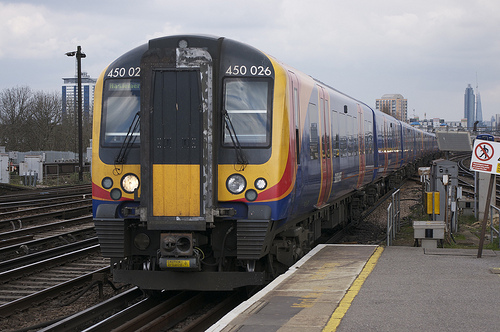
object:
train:
[90, 33, 437, 296]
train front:
[91, 36, 288, 292]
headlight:
[227, 174, 247, 193]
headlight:
[121, 173, 140, 193]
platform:
[197, 241, 499, 331]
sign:
[470, 137, 499, 176]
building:
[374, 93, 408, 125]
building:
[61, 70, 95, 124]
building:
[464, 82, 475, 132]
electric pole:
[73, 45, 86, 179]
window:
[101, 77, 139, 148]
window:
[224, 78, 272, 148]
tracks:
[0, 152, 499, 331]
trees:
[3, 84, 51, 152]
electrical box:
[427, 158, 460, 232]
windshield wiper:
[221, 110, 247, 165]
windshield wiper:
[114, 111, 141, 165]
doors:
[316, 83, 333, 203]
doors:
[357, 104, 365, 186]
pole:
[477, 174, 497, 259]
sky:
[1, 0, 499, 126]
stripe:
[316, 245, 385, 332]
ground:
[2, 152, 496, 331]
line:
[201, 245, 329, 332]